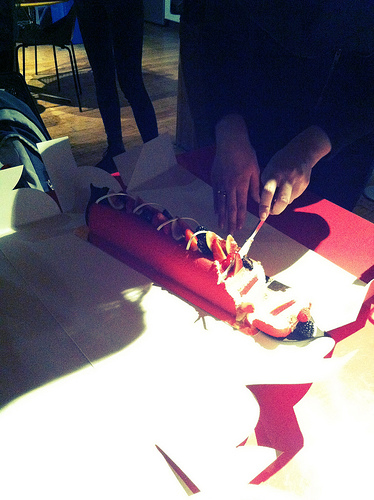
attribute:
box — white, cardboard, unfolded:
[1, 131, 374, 498]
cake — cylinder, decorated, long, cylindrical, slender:
[86, 183, 315, 340]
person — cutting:
[179, 1, 373, 236]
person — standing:
[73, 0, 158, 175]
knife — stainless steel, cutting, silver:
[217, 219, 266, 286]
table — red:
[108, 144, 373, 285]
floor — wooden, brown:
[16, 20, 183, 167]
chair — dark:
[14, 1, 82, 113]